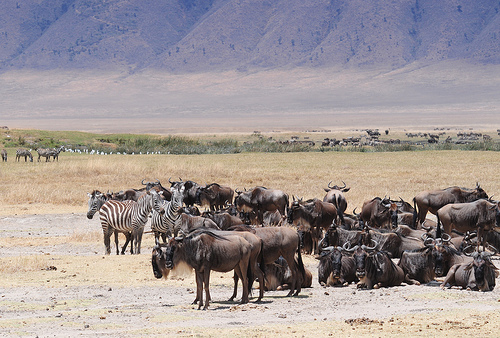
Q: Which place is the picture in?
A: It is at the field.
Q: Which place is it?
A: It is a field.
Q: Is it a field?
A: Yes, it is a field.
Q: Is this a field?
A: Yes, it is a field.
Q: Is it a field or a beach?
A: It is a field.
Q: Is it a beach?
A: No, it is a field.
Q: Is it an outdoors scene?
A: Yes, it is outdoors.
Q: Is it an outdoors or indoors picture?
A: It is outdoors.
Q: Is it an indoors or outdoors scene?
A: It is outdoors.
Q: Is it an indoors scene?
A: No, it is outdoors.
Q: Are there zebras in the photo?
A: Yes, there are zebras.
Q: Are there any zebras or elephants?
A: Yes, there are zebras.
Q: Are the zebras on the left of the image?
A: Yes, the zebras are on the left of the image.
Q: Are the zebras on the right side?
A: No, the zebras are on the left of the image.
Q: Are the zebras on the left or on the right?
A: The zebras are on the left of the image.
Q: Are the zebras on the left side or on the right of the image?
A: The zebras are on the left of the image.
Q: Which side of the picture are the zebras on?
A: The zebras are on the left of the image.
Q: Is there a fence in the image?
A: No, there are no fences.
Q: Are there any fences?
A: No, there are no fences.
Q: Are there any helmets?
A: No, there are no helmets.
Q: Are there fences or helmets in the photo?
A: No, there are no helmets or fences.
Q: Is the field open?
A: Yes, the field is open.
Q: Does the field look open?
A: Yes, the field is open.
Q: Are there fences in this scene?
A: No, there are no fences.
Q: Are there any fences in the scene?
A: No, there are no fences.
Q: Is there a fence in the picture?
A: No, there are no fences.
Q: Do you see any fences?
A: No, there are no fences.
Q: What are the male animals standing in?
A: The animals are standing in the dirt.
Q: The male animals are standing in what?
A: The animals are standing in the dirt.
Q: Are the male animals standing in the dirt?
A: Yes, the animals are standing in the dirt.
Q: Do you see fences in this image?
A: No, there are no fences.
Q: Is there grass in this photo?
A: Yes, there is grass.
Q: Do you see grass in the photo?
A: Yes, there is grass.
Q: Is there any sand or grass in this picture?
A: Yes, there is grass.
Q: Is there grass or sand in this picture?
A: Yes, there is grass.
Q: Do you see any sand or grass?
A: Yes, there is grass.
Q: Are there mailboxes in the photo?
A: No, there are no mailboxes.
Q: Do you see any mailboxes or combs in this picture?
A: No, there are no mailboxes or combs.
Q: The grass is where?
A: The grass is on the ground.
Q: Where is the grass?
A: The grass is on the ground.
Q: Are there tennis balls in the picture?
A: No, there are no tennis balls.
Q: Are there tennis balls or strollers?
A: No, there are no tennis balls or strollers.